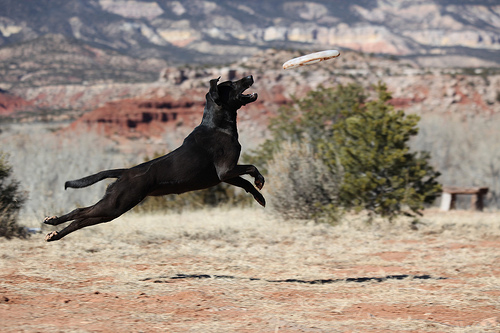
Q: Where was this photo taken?
A: In the desert.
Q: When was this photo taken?
A: Daytime.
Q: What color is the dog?
A: Black.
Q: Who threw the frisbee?
A: Dog's owner.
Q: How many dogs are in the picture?
A: One.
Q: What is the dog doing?
A: Catching a frisbee.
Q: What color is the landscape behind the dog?
A: Red, grey, and black.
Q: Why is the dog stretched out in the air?
A: It's catching a frisbee.